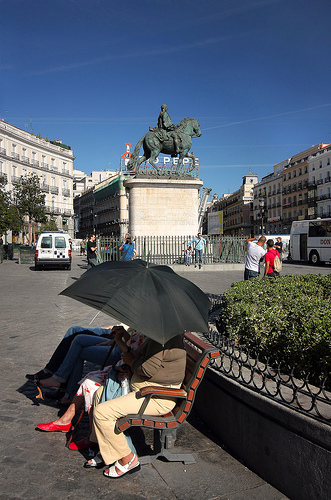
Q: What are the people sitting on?
A: A bench.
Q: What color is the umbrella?
A: Black.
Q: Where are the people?
A: On a bench.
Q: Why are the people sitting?
A: To rest.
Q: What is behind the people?
A: A bush.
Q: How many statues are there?
A: One.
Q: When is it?
A: During the day.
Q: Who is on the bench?
A: A group of ladies.